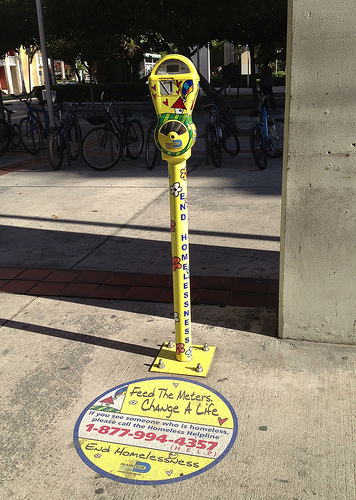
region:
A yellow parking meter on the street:
[146, 52, 215, 373]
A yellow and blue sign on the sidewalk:
[70, 377, 242, 484]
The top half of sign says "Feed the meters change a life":
[128, 376, 236, 430]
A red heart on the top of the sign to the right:
[215, 414, 231, 425]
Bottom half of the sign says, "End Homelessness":
[84, 439, 215, 475]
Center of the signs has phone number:
[84, 419, 222, 450]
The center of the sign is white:
[78, 408, 226, 455]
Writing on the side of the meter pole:
[178, 190, 193, 346]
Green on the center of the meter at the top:
[153, 114, 192, 155]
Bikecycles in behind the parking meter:
[23, 92, 282, 178]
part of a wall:
[285, 415, 300, 432]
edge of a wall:
[285, 323, 292, 345]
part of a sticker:
[181, 428, 188, 448]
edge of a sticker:
[198, 408, 201, 413]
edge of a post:
[187, 335, 201, 342]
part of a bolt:
[193, 365, 204, 371]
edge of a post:
[199, 374, 204, 385]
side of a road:
[259, 420, 271, 437]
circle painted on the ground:
[73, 376, 237, 484]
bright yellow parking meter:
[147, 52, 217, 376]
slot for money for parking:
[159, 78, 172, 95]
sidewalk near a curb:
[242, 332, 354, 492]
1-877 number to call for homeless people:
[76, 410, 221, 456]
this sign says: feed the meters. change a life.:
[128, 379, 234, 417]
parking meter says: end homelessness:
[176, 191, 189, 346]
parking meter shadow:
[0, 317, 176, 361]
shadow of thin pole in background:
[0, 213, 278, 243]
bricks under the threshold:
[8, 265, 168, 298]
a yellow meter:
[143, 50, 219, 379]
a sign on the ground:
[72, 371, 239, 492]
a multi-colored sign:
[69, 371, 239, 490]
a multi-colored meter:
[145, 53, 221, 376]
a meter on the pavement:
[145, 54, 218, 384]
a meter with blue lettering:
[137, 51, 221, 378]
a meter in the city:
[143, 51, 215, 379]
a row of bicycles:
[1, 83, 284, 175]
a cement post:
[270, 3, 354, 348]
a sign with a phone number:
[69, 373, 240, 486]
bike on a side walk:
[244, 89, 270, 174]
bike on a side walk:
[195, 96, 237, 156]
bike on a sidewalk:
[86, 90, 140, 170]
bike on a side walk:
[48, 92, 75, 173]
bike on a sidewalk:
[19, 80, 35, 160]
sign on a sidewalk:
[69, 365, 237, 486]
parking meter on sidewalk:
[128, 50, 223, 363]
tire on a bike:
[243, 121, 265, 168]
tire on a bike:
[198, 120, 212, 165]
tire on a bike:
[78, 128, 122, 169]